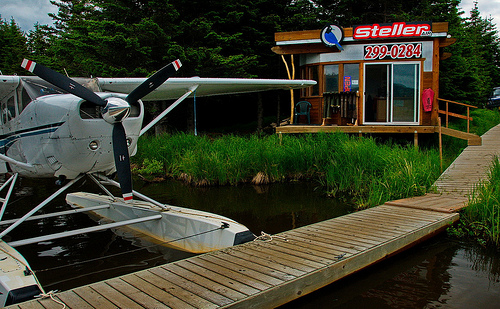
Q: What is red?
A: Office.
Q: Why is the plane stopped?
A: Landed.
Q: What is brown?
A: Dock.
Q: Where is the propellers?
A: On the nose of the plane.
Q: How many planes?
A: One.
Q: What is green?
A: Trees.